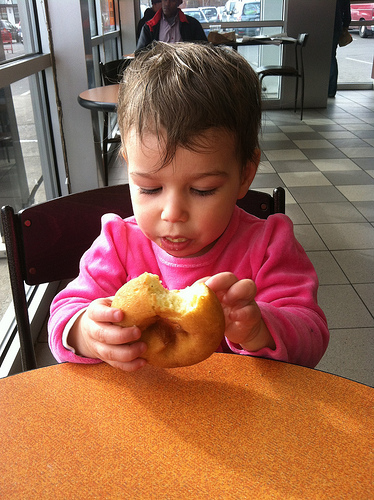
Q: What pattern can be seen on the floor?
A: Checkers.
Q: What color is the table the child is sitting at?
A: Orange.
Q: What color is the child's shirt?
A: Pink.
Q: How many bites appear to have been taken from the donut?
A: One.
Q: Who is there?
A: Little girl.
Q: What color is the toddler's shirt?
A: Pink.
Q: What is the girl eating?
A: Donut.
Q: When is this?
A: Afternoon.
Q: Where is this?
A: Cafe.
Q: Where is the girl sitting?
A: Chair.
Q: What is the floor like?
A: Tiled.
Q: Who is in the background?
A: A man.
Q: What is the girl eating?
A: Donut.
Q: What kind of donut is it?
A: Plain.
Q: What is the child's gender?
A: Girl.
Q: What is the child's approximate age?
A: 2.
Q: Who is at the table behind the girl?
A: A man with a jacket.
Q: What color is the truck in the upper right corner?
A: Red.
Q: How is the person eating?
A: With fingers.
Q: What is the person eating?
A: Donut.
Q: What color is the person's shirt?
A: Pink.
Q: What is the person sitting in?
A: Chair.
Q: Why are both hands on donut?
A: To hold it.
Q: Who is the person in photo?
A: Small child.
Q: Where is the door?
A: In backgound to right.